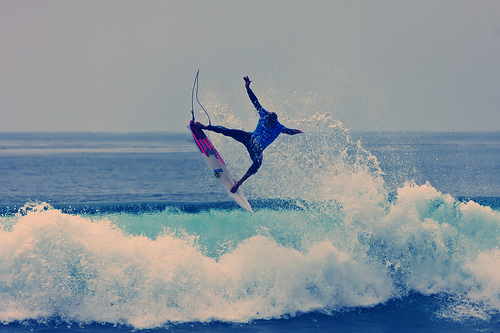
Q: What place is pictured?
A: It is an ocean.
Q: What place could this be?
A: It is an ocean.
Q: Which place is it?
A: It is an ocean.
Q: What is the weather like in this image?
A: It is clear.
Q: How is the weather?
A: It is clear.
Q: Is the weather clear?
A: Yes, it is clear.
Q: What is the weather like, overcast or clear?
A: It is clear.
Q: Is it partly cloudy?
A: No, it is clear.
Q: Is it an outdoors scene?
A: Yes, it is outdoors.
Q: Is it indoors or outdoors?
A: It is outdoors.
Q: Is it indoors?
A: No, it is outdoors.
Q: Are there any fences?
A: No, there are no fences.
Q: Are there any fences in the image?
A: No, there are no fences.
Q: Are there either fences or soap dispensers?
A: No, there are no fences or soap dispensers.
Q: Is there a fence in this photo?
A: No, there are no fences.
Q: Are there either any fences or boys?
A: No, there are no fences or boys.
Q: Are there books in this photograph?
A: No, there are no books.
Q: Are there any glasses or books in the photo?
A: No, there are no books or glasses.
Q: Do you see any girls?
A: No, there are no girls.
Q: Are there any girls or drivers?
A: No, there are no girls or drivers.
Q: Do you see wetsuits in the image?
A: Yes, there is a wetsuit.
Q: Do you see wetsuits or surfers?
A: Yes, there is a wetsuit.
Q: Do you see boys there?
A: No, there are no boys.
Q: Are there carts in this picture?
A: No, there are no carts.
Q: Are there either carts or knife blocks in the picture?
A: No, there are no carts or knife blocks.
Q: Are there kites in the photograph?
A: No, there are no kites.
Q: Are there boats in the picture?
A: No, there are no boats.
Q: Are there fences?
A: No, there are no fences.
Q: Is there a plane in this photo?
A: No, there are no airplanes.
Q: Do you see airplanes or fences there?
A: No, there are no airplanes or fences.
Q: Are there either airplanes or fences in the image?
A: No, there are no airplanes or fences.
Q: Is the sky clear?
A: Yes, the sky is clear.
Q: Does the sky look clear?
A: Yes, the sky is clear.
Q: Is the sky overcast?
A: No, the sky is clear.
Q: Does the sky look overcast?
A: No, the sky is clear.